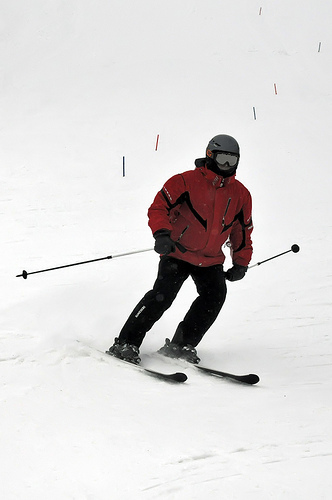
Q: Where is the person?
A: On the slope.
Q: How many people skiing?
A: One.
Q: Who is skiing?
A: A man.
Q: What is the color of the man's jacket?
A: Red.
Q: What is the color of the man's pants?
A: Black.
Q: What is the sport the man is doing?
A: Skiing.